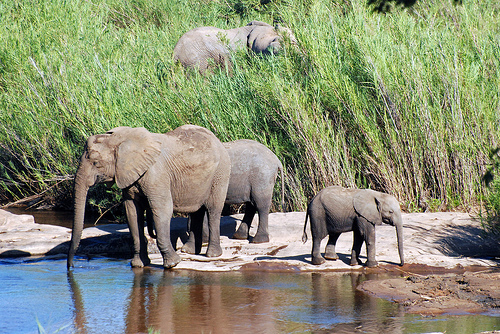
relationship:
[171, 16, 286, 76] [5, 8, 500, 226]
elephant in grass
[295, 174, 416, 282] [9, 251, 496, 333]
elephant near water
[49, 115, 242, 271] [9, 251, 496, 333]
elephant drinking water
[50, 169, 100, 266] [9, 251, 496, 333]
trunk in water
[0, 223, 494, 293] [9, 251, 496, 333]
bank of river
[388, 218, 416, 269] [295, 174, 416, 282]
trunk of elephant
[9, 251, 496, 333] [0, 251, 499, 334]
hole for water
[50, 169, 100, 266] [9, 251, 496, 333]
trunk reaching water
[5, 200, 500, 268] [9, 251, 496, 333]
ground by hole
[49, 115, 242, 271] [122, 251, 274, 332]
elephant has reflection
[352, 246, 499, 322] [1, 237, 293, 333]
rocks in stream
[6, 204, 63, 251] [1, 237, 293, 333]
rocks by stream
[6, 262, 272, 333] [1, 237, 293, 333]
ripples in stream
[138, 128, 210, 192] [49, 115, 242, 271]
wrinkles on elephant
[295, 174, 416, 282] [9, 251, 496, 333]
elephant beside water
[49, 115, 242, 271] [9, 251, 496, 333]
elephant beside water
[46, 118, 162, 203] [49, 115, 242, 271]
head of elephant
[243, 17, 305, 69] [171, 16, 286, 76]
head of elephant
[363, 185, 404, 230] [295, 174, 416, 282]
head of elephant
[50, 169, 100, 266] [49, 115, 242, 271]
trunk of elephant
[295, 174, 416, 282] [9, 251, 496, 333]
elephant by water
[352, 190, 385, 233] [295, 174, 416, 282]
ear of elephant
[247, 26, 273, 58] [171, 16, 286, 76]
ear of elephant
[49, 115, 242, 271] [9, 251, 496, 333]
elephant in water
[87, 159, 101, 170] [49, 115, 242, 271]
eye on elephant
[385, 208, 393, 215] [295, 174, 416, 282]
eye on elephant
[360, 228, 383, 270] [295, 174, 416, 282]
leg on elephant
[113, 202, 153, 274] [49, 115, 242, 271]
leg on elephant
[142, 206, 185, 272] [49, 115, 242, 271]
leg on elephant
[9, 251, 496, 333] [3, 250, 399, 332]
pool of water